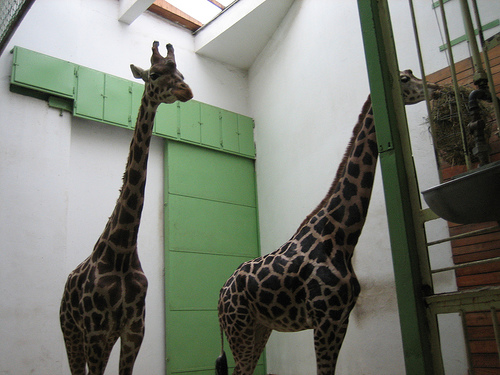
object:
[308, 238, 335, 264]
spot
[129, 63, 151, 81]
ear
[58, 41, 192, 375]
giraffe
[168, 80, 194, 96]
nose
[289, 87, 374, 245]
mane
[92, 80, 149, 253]
mane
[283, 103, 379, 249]
neck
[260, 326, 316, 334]
edge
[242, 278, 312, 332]
stomach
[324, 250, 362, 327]
chest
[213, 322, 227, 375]
tail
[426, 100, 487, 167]
hay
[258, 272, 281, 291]
spots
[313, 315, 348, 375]
legs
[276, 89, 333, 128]
floor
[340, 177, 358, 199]
spot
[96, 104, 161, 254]
neck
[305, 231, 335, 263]
spot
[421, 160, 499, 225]
basin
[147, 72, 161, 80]
eye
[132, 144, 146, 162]
spot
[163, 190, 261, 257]
green panel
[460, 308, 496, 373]
wood paneling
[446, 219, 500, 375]
wall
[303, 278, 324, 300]
spots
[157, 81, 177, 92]
onions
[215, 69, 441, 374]
eating giraffe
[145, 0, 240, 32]
skylight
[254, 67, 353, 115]
wall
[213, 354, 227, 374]
tuft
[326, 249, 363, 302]
part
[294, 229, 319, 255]
spot